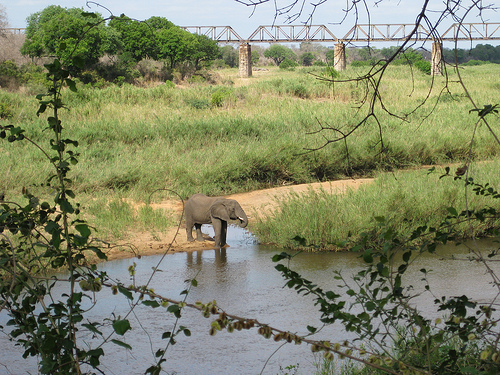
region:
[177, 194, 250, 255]
an elephant standing on the bank of a river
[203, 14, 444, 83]
a bridge on cement pillars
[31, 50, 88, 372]
the leaves of a tree branch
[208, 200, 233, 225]
the ear of an elephant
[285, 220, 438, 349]
the branches of a bush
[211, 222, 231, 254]
the front legs of an elephant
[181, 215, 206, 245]
the hind leg of an elephant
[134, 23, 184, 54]
the leaves of a tree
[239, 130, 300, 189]
the tall grass beside a road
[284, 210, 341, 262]
the tall grass on the bank of a river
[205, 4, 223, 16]
this is the sky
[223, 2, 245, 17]
the sky is blue in color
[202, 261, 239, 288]
this is the water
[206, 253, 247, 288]
the water has some ripples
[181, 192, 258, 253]
this is an elephant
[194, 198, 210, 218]
the fur is grey in color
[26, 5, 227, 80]
these are some trees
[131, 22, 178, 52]
the leaves are green in color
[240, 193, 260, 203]
this is a path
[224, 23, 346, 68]
this is a bridge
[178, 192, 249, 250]
Young elephant standing near water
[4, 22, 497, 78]
Above ground railroad tracks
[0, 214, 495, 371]
Medium sized stream of water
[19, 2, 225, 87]
Copse of trees in the background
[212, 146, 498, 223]
Dirt trail along the side of the stream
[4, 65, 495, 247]
Tall weeds and grassy area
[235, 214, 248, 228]
Trunk and tusk of a baby elephant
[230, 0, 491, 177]
Bare tree branches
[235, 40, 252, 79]
A post supporting the rail bridge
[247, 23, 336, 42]
Section of Pratt truss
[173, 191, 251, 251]
An elephant standing up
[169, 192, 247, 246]
The elephant is near water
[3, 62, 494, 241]
pretty green grass around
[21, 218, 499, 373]
Water in the middle of the grass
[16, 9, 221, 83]
trees bunched together around the elephant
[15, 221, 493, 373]
The water looks dark brown in color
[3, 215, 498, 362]
The water is very calm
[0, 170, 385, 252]
dirt around the elephant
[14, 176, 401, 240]
The dirt is tan in color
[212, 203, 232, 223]
The ear of the elephant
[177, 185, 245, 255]
elephant at the water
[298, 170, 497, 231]
grass growing beside the water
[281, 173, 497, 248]
the grass is tall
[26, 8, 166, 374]
vines growing in the foreground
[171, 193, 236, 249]
the elephant is drinking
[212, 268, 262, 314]
the water is calm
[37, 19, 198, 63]
trees with green leaves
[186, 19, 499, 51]
the bridge in the background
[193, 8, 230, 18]
the clear blue sky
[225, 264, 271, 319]
the water is opaque